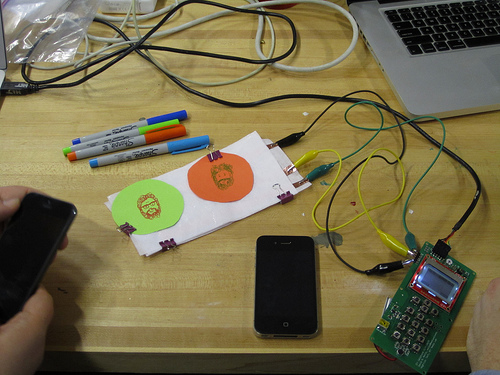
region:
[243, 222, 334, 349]
A cell phone on the table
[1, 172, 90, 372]
Person is holding a cell phone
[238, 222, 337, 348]
The cell phone is black in color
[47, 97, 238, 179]
Markers are on the table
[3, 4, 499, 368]
Table is made of wood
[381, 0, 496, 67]
The laptop keyboard is black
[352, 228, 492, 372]
A electronic device on the table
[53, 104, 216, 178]
Four markers are on the table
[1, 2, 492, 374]
Photo was taken indoors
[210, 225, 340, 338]
the phone is off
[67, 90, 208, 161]
colored markers on the table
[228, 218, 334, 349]
the phone is black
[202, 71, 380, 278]
the table is tan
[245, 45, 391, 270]
the table is made of wood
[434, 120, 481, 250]
the wire is black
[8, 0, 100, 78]
a plastic bag on the table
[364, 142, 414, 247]
a green and yellow wire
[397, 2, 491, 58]
the keys are black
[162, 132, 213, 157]
the top of the marker is blue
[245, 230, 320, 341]
a smart phone on a table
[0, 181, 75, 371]
two hands holding a smartphone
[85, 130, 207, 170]
a light blue marker pen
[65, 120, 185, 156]
an orange marker pen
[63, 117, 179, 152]
a green marker pen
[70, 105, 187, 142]
a blue marker pen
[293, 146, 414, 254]
a yellow cord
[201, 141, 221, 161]
a purple clip holding paper together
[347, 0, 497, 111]
the keyboard of a laptop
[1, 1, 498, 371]
a light brown wood table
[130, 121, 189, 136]
Green sharpie on table.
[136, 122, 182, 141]
Orange sharpie on table.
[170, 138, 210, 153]
Blue sharpie sitting on table.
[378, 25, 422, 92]
Silver laptop sitting on table.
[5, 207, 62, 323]
Person holding cell phone.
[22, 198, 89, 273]
Cell phone is black.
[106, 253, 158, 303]
Table is light brown.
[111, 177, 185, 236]
Green circle with a drawing of a face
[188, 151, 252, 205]
Drawing of a face in an orange circle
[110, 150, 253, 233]
Two circle pieces of paper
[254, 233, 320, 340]
Rectangular black cellphone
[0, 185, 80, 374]
Person holding a smartphone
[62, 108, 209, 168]
Four Sharpie markers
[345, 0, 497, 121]
Grey laptop with black keyboard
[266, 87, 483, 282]
Measuring the electricity of paper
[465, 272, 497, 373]
Hand on a table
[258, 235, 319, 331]
a cellphone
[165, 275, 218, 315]
a counter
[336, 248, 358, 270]
a black cord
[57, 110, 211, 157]
markers on the desk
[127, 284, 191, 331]
the desk is brown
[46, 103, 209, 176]
four markers of assorted colors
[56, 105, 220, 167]
four markers of assorted colors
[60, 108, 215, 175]
four markers of assorted colors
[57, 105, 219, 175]
four markers of assorted colors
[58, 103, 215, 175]
four markers of assorted colors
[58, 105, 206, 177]
four markers of assorted colors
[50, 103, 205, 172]
four markers of assorted colors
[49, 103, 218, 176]
four markers of assorted colors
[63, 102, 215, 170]
four markers of assorted colors